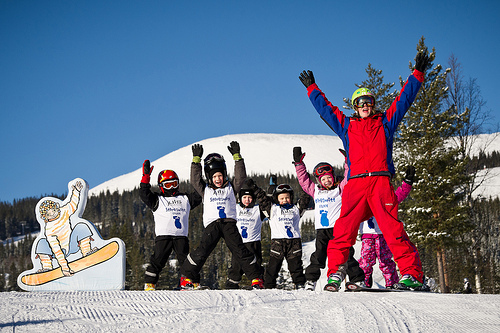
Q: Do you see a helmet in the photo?
A: Yes, there is a helmet.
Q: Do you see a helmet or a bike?
A: Yes, there is a helmet.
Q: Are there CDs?
A: No, there are no cds.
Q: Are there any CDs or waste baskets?
A: No, there are no CDs or waste baskets.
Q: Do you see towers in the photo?
A: No, there are no towers.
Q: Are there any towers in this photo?
A: No, there are no towers.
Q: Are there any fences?
A: No, there are no fences.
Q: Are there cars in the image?
A: No, there are no cars.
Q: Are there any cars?
A: No, there are no cars.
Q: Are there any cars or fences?
A: No, there are no cars or fences.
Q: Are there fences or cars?
A: No, there are no cars or fences.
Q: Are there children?
A: Yes, there is a child.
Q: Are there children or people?
A: Yes, there is a child.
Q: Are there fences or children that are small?
A: Yes, the child is small.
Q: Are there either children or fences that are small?
A: Yes, the child is small.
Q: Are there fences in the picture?
A: No, there are no fences.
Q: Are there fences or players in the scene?
A: No, there are no fences or players.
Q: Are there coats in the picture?
A: Yes, there is a coat.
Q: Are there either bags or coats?
A: Yes, there is a coat.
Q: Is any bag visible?
A: No, there are no bags.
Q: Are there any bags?
A: No, there are no bags.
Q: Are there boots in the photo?
A: Yes, there are boots.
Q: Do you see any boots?
A: Yes, there are boots.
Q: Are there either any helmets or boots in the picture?
A: Yes, there are boots.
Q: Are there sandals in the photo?
A: No, there are no sandals.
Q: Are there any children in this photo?
A: Yes, there is a child.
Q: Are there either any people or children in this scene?
A: Yes, there is a child.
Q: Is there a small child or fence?
A: Yes, there is a small child.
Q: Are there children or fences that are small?
A: Yes, the child is small.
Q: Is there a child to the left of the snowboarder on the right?
A: Yes, there is a child to the left of the snowboarder.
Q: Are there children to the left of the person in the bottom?
A: Yes, there is a child to the left of the snowboarder.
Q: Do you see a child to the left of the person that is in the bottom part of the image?
A: Yes, there is a child to the left of the snowboarder.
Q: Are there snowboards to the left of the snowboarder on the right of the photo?
A: No, there is a child to the left of the snowboarder.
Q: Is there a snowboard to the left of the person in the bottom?
A: No, there is a child to the left of the snowboarder.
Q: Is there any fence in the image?
A: No, there are no fences.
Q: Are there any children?
A: Yes, there is a child.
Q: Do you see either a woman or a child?
A: Yes, there is a child.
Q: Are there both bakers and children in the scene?
A: No, there is a child but no bakers.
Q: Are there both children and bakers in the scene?
A: No, there is a child but no bakers.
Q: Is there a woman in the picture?
A: No, there are no women.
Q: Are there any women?
A: No, there are no women.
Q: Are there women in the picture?
A: No, there are no women.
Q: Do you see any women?
A: No, there are no women.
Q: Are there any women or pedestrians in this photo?
A: No, there are no women or pedestrians.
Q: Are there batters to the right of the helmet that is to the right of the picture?
A: No, there is a child to the right of the helmet.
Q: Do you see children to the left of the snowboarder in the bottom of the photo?
A: Yes, there is a child to the left of the snowboarder.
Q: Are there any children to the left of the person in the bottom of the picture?
A: Yes, there is a child to the left of the snowboarder.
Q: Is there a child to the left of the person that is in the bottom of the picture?
A: Yes, there is a child to the left of the snowboarder.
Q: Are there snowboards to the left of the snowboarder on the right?
A: No, there is a child to the left of the snowboarder.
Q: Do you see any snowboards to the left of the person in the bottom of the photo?
A: No, there is a child to the left of the snowboarder.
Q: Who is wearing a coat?
A: The child is wearing a coat.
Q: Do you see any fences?
A: No, there are no fences.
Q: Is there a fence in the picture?
A: No, there are no fences.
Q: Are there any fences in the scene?
A: No, there are no fences.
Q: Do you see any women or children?
A: Yes, there is a child.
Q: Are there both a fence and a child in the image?
A: No, there is a child but no fences.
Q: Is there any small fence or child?
A: Yes, there is a small child.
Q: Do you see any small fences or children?
A: Yes, there is a small child.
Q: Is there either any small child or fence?
A: Yes, there is a small child.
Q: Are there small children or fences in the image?
A: Yes, there is a small child.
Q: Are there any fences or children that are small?
A: Yes, the child is small.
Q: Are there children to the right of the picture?
A: Yes, there is a child to the right of the picture.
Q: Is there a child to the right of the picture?
A: Yes, there is a child to the right of the picture.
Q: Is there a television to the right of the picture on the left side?
A: No, there is a child to the right of the picture.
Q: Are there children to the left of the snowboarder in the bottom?
A: Yes, there is a child to the left of the snowboarder.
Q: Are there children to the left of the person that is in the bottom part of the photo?
A: Yes, there is a child to the left of the snowboarder.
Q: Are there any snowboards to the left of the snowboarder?
A: No, there is a child to the left of the snowboarder.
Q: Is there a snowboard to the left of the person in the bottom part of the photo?
A: No, there is a child to the left of the snowboarder.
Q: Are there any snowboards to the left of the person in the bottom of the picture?
A: No, there is a child to the left of the snowboarder.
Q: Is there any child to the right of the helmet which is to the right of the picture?
A: Yes, there is a child to the right of the helmet.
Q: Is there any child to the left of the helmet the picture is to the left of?
A: No, the child is to the right of the helmet.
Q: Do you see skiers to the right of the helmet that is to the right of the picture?
A: No, there is a child to the right of the helmet.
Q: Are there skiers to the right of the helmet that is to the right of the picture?
A: No, there is a child to the right of the helmet.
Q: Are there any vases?
A: No, there are no vases.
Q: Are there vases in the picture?
A: No, there are no vases.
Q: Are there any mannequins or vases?
A: No, there are no vases or mannequins.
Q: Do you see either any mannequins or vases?
A: No, there are no vases or mannequins.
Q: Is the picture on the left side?
A: Yes, the picture is on the left of the image.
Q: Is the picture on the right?
A: No, the picture is on the left of the image.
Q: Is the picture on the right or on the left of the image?
A: The picture is on the left of the image.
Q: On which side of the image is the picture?
A: The picture is on the left of the image.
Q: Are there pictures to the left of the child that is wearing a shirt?
A: Yes, there is a picture to the left of the child.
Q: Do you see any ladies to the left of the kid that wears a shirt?
A: No, there is a picture to the left of the child.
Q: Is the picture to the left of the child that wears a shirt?
A: Yes, the picture is to the left of the child.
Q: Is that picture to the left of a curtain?
A: No, the picture is to the left of the child.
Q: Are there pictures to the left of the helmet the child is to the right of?
A: Yes, there is a picture to the left of the helmet.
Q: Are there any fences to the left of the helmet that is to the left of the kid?
A: No, there is a picture to the left of the helmet.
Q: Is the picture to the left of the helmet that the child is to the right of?
A: Yes, the picture is to the left of the helmet.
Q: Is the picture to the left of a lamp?
A: No, the picture is to the left of the helmet.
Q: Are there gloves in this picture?
A: Yes, there are gloves.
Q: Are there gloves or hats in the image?
A: Yes, there are gloves.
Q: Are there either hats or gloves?
A: Yes, there are gloves.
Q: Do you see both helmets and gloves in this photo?
A: Yes, there are both gloves and a helmet.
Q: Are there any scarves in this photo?
A: No, there are no scarves.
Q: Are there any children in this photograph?
A: Yes, there is a child.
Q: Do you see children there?
A: Yes, there is a child.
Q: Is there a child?
A: Yes, there is a child.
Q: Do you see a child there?
A: Yes, there is a child.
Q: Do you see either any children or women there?
A: Yes, there is a child.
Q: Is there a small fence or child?
A: Yes, there is a small child.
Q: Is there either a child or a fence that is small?
A: Yes, the child is small.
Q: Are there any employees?
A: No, there are no employees.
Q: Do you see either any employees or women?
A: No, there are no employees or women.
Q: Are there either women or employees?
A: No, there are no employees or women.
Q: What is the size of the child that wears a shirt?
A: The child is small.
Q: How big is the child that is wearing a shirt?
A: The kid is small.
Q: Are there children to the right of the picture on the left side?
A: Yes, there is a child to the right of the picture.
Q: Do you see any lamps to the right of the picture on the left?
A: No, there is a child to the right of the picture.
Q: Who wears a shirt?
A: The kid wears a shirt.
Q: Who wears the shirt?
A: The kid wears a shirt.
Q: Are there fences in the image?
A: No, there are no fences.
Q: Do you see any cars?
A: No, there are no cars.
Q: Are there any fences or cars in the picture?
A: No, there are no cars or fences.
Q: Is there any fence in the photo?
A: No, there are no fences.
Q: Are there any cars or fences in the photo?
A: No, there are no fences or cars.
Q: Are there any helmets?
A: Yes, there is a helmet.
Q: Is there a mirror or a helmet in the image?
A: Yes, there is a helmet.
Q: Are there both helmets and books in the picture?
A: No, there is a helmet but no books.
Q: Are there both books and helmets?
A: No, there is a helmet but no books.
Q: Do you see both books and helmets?
A: No, there is a helmet but no books.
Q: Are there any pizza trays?
A: No, there are no pizza trays.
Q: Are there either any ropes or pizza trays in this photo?
A: No, there are no pizza trays or ropes.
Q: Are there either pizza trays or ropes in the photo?
A: No, there are no pizza trays or ropes.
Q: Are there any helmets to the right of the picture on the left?
A: Yes, there is a helmet to the right of the picture.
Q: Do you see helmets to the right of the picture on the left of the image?
A: Yes, there is a helmet to the right of the picture.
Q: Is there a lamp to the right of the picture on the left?
A: No, there is a helmet to the right of the picture.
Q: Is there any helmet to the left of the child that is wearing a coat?
A: Yes, there is a helmet to the left of the child.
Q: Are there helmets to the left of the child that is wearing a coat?
A: Yes, there is a helmet to the left of the child.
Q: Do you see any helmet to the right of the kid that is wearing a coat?
A: No, the helmet is to the left of the child.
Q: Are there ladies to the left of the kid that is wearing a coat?
A: No, there is a helmet to the left of the kid.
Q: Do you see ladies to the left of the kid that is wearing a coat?
A: No, there is a helmet to the left of the kid.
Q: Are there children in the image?
A: Yes, there is a child.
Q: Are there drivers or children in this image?
A: Yes, there is a child.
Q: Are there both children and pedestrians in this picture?
A: No, there is a child but no pedestrians.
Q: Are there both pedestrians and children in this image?
A: No, there is a child but no pedestrians.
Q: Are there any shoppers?
A: No, there are no shoppers.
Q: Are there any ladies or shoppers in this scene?
A: No, there are no shoppers or ladies.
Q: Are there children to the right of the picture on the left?
A: Yes, there is a child to the right of the picture.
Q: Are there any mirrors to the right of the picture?
A: No, there is a child to the right of the picture.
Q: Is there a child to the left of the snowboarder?
A: Yes, there is a child to the left of the snowboarder.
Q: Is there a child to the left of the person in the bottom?
A: Yes, there is a child to the left of the snowboarder.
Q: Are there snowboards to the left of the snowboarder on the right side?
A: No, there is a child to the left of the snowboarder.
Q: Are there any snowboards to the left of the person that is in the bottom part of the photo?
A: No, there is a child to the left of the snowboarder.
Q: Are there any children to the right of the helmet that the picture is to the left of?
A: Yes, there is a child to the right of the helmet.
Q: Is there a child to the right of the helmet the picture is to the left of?
A: Yes, there is a child to the right of the helmet.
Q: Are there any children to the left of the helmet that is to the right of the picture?
A: No, the child is to the right of the helmet.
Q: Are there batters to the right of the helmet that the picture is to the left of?
A: No, there is a child to the right of the helmet.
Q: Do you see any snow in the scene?
A: Yes, there is snow.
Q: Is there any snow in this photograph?
A: Yes, there is snow.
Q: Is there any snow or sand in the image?
A: Yes, there is snow.